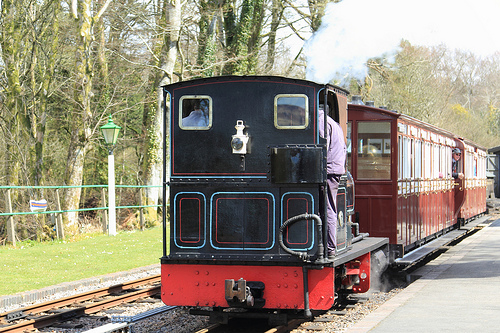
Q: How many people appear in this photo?
A: One.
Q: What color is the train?
A: Black.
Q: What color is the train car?
A: Red.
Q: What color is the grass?
A: Green.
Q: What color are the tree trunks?
A: Brown.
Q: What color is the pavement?
A: Gray.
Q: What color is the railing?
A: Brown.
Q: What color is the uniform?
A: Gray.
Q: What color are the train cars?
A: Red.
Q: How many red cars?
A: Two.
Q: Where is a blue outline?
A: On back of train.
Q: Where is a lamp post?
A: Left side in grass.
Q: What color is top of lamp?
A: Green.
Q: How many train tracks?
A: Two.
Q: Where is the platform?
A: Right side of train.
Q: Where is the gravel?
A: On and around tracks.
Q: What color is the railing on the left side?
A: Green.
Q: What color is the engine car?
A: Black and red.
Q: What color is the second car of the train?
A: Red.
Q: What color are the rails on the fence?
A: Green.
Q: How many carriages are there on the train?
A: Two.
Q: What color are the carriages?
A: Red.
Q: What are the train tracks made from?
A: Metal.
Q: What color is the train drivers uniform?
A: Blue.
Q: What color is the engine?
A: Black.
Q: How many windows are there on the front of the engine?
A: Two.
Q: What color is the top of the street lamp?
A: Green.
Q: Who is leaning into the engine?
A: The train driver.